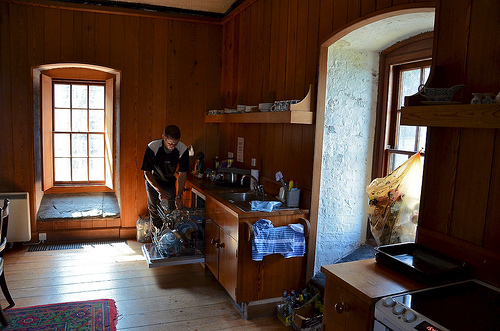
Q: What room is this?
A: It is a kitchen.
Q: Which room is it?
A: It is a kitchen.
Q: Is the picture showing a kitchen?
A: Yes, it is showing a kitchen.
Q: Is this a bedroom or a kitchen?
A: It is a kitchen.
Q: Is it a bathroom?
A: No, it is a kitchen.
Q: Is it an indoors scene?
A: Yes, it is indoors.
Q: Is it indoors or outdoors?
A: It is indoors.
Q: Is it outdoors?
A: No, it is indoors.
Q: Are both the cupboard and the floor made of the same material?
A: Yes, both the cupboard and the floor are made of wood.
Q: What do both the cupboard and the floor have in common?
A: The material, both the cupboard and the floor are wooden.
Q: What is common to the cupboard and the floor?
A: The material, both the cupboard and the floor are wooden.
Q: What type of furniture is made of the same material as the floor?
A: The cupboard is made of the same material as the floor.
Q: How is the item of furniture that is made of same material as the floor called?
A: The piece of furniture is a cupboard.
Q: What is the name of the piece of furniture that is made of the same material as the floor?
A: The piece of furniture is a cupboard.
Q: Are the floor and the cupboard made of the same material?
A: Yes, both the floor and the cupboard are made of wood.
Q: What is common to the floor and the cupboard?
A: The material, both the floor and the cupboard are wooden.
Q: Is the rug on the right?
A: No, the rug is on the left of the image.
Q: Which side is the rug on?
A: The rug is on the left of the image.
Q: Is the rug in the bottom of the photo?
A: Yes, the rug is in the bottom of the image.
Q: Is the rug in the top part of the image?
A: No, the rug is in the bottom of the image.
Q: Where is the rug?
A: The rug is on the floor.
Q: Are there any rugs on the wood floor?
A: Yes, there is a rug on the floor.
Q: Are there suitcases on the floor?
A: No, there is a rug on the floor.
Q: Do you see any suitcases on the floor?
A: No, there is a rug on the floor.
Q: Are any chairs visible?
A: Yes, there is a chair.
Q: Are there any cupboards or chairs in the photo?
A: Yes, there is a chair.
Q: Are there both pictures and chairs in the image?
A: No, there is a chair but no pictures.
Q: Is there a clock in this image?
A: No, there are no clocks.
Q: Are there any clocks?
A: No, there are no clocks.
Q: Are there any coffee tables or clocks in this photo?
A: No, there are no clocks or coffee tables.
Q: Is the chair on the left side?
A: Yes, the chair is on the left of the image.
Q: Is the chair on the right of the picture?
A: No, the chair is on the left of the image.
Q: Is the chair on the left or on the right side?
A: The chair is on the left of the image.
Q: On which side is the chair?
A: The chair is on the left of the image.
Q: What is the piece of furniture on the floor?
A: The piece of furniture is a chair.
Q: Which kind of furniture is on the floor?
A: The piece of furniture is a chair.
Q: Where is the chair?
A: The chair is on the floor.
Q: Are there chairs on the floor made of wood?
A: Yes, there is a chair on the floor.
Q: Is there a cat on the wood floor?
A: No, there is a chair on the floor.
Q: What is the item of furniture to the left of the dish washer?
A: The piece of furniture is a chair.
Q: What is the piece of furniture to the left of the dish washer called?
A: The piece of furniture is a chair.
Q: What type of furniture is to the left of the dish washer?
A: The piece of furniture is a chair.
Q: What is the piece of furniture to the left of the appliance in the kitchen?
A: The piece of furniture is a chair.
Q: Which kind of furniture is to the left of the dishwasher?
A: The piece of furniture is a chair.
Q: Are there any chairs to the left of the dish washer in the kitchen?
A: Yes, there is a chair to the left of the dishwasher.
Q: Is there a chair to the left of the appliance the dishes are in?
A: Yes, there is a chair to the left of the dishwasher.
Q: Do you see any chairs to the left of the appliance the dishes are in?
A: Yes, there is a chair to the left of the dishwasher.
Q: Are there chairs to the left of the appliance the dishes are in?
A: Yes, there is a chair to the left of the dishwasher.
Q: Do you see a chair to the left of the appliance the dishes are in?
A: Yes, there is a chair to the left of the dishwasher.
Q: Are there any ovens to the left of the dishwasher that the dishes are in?
A: No, there is a chair to the left of the dishwasher.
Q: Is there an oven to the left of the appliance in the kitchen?
A: No, there is a chair to the left of the dishwasher.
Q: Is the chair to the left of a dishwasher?
A: Yes, the chair is to the left of a dishwasher.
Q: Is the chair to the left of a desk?
A: No, the chair is to the left of a dishwasher.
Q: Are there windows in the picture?
A: Yes, there is a window.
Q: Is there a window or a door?
A: Yes, there is a window.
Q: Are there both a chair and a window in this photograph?
A: Yes, there are both a window and a chair.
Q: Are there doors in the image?
A: No, there are no doors.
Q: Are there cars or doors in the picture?
A: No, there are no doors or cars.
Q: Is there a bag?
A: Yes, there is a bag.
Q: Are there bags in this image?
A: Yes, there is a bag.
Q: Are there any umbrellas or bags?
A: Yes, there is a bag.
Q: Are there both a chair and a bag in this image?
A: Yes, there are both a bag and a chair.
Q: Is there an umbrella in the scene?
A: No, there are no umbrellas.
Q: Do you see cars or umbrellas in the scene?
A: No, there are no umbrellas or cars.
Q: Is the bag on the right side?
A: Yes, the bag is on the right of the image.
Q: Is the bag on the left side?
A: No, the bag is on the right of the image.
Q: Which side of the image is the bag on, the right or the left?
A: The bag is on the right of the image.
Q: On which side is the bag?
A: The bag is on the right of the image.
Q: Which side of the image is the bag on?
A: The bag is on the right of the image.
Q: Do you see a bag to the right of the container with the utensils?
A: Yes, there is a bag to the right of the container.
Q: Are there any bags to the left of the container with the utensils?
A: No, the bag is to the right of the container.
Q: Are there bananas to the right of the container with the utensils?
A: No, there is a bag to the right of the container.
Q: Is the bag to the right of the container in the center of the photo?
A: Yes, the bag is to the right of the container.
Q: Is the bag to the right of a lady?
A: No, the bag is to the right of the container.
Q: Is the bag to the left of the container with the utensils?
A: No, the bag is to the right of the container.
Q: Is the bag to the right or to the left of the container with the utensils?
A: The bag is to the right of the container.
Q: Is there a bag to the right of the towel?
A: Yes, there is a bag to the right of the towel.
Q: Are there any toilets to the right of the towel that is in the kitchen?
A: No, there is a bag to the right of the towel.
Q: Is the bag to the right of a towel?
A: Yes, the bag is to the right of a towel.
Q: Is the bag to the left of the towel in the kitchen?
A: No, the bag is to the right of the towel.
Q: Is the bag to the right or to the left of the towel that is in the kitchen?
A: The bag is to the right of the towel.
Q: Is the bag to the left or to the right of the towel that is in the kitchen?
A: The bag is to the right of the towel.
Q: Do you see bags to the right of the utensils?
A: Yes, there is a bag to the right of the utensils.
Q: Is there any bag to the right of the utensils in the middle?
A: Yes, there is a bag to the right of the utensils.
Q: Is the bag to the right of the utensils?
A: Yes, the bag is to the right of the utensils.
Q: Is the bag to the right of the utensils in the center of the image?
A: Yes, the bag is to the right of the utensils.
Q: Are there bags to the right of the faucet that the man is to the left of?
A: Yes, there is a bag to the right of the tap.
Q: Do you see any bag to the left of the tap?
A: No, the bag is to the right of the tap.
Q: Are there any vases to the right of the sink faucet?
A: No, there is a bag to the right of the faucet.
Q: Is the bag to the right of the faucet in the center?
A: Yes, the bag is to the right of the faucet.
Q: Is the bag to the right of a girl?
A: No, the bag is to the right of the faucet.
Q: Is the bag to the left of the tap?
A: No, the bag is to the right of the tap.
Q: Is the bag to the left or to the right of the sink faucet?
A: The bag is to the right of the tap.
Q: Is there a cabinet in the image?
A: Yes, there is a cabinet.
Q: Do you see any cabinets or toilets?
A: Yes, there is a cabinet.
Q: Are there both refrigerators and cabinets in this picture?
A: No, there is a cabinet but no refrigerators.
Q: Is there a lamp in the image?
A: No, there are no lamps.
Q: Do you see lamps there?
A: No, there are no lamps.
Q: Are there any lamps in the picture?
A: No, there are no lamps.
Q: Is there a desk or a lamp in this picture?
A: No, there are no lamps or desks.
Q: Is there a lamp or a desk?
A: No, there are no lamps or desks.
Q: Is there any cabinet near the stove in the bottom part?
A: Yes, there is a cabinet near the stove.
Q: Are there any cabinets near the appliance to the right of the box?
A: Yes, there is a cabinet near the stove.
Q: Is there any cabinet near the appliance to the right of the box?
A: Yes, there is a cabinet near the stove.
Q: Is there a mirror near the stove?
A: No, there is a cabinet near the stove.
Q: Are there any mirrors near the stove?
A: No, there is a cabinet near the stove.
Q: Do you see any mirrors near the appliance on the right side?
A: No, there is a cabinet near the stove.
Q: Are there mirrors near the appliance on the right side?
A: No, there is a cabinet near the stove.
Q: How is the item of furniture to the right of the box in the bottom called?
A: The piece of furniture is a cabinet.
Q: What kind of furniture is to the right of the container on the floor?
A: The piece of furniture is a cabinet.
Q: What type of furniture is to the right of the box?
A: The piece of furniture is a cabinet.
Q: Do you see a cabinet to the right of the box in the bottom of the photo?
A: Yes, there is a cabinet to the right of the box.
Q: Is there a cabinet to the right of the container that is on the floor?
A: Yes, there is a cabinet to the right of the box.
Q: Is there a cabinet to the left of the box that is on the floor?
A: No, the cabinet is to the right of the box.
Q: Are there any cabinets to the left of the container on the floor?
A: No, the cabinet is to the right of the box.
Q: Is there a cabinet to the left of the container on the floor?
A: No, the cabinet is to the right of the box.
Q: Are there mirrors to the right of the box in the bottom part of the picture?
A: No, there is a cabinet to the right of the box.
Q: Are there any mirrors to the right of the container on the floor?
A: No, there is a cabinet to the right of the box.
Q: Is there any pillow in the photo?
A: No, there are no pillows.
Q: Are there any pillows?
A: No, there are no pillows.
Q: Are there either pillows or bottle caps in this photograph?
A: No, there are no pillows or bottle caps.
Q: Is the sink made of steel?
A: Yes, the sink is made of steel.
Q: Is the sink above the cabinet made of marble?
A: No, the sink is made of steel.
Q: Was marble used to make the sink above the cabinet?
A: No, the sink is made of steel.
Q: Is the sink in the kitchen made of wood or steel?
A: The sink is made of steel.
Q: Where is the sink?
A: The sink is in the kitchen.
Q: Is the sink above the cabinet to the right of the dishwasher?
A: Yes, the sink is above the cabinet.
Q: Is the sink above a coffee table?
A: No, the sink is above the cabinet.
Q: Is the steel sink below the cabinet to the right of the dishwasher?
A: No, the sink is above the cabinet.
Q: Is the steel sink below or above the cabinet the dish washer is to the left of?
A: The sink is above the cabinet.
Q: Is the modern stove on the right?
A: Yes, the stove is on the right of the image.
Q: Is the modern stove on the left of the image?
A: No, the stove is on the right of the image.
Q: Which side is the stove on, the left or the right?
A: The stove is on the right of the image.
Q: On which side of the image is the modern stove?
A: The stove is on the right of the image.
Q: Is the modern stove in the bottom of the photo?
A: Yes, the stove is in the bottom of the image.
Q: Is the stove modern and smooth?
A: Yes, the stove is modern and smooth.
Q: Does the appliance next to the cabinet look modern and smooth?
A: Yes, the stove is modern and smooth.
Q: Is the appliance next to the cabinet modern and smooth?
A: Yes, the stove is modern and smooth.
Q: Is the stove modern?
A: Yes, the stove is modern.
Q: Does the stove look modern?
A: Yes, the stove is modern.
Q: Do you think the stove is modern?
A: Yes, the stove is modern.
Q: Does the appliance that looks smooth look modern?
A: Yes, the stove is modern.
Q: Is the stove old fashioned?
A: No, the stove is modern.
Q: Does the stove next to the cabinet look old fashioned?
A: No, the stove is modern.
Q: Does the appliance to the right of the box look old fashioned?
A: No, the stove is modern.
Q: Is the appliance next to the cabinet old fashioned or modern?
A: The stove is modern.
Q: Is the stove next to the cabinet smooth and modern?
A: Yes, the stove is smooth and modern.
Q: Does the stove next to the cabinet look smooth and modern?
A: Yes, the stove is smooth and modern.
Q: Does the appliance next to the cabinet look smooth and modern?
A: Yes, the stove is smooth and modern.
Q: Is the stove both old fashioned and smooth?
A: No, the stove is smooth but modern.